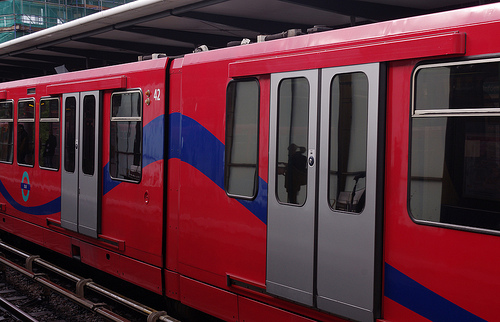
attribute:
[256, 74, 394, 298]
door —  silver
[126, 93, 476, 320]
stripe —  blue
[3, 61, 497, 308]
train car —  train's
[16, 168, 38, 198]
logo — circular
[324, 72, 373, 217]
window —   small 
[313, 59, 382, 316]
door —  train car's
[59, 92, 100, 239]
door — silver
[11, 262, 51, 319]
rocks — small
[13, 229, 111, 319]
track — brown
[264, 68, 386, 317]
door — silver, grey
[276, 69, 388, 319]
door —  train's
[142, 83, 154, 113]
lights —   round ,  train's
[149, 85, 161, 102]
number 42 —  number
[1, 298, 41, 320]
metal track —  metal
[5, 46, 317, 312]
train — red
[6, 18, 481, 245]
train — red, blue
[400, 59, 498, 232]
window — black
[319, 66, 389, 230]
window —  of train door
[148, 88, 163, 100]
number — white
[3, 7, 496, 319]
train cars —  two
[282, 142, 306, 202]
reflection —  of  person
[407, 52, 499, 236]
window — black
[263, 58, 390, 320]
grey door —  gray,  double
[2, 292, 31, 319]
track — of rust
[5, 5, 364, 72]
ceiling — green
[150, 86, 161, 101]
number — 42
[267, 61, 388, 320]
silver doors —  silver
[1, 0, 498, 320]
train —  metal, red, blue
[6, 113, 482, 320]
stripe — blue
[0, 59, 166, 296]
car —  of train